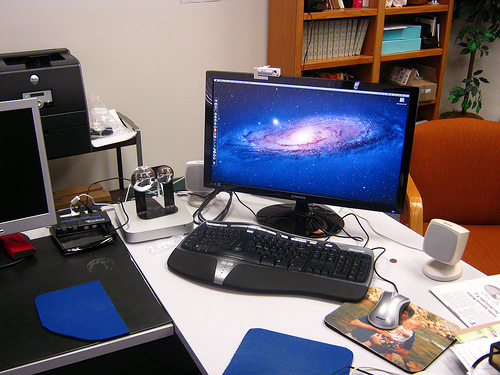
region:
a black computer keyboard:
[166, 217, 374, 304]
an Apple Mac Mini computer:
[113, 189, 195, 244]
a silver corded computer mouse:
[368, 287, 411, 329]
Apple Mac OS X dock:
[212, 97, 217, 168]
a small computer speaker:
[419, 217, 468, 281]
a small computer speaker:
[183, 158, 216, 206]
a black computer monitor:
[201, 68, 421, 239]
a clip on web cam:
[252, 64, 281, 81]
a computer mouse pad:
[324, 283, 461, 370]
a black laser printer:
[2, 43, 90, 158]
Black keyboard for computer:
[165, 216, 375, 302]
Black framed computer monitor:
[200, 63, 415, 213]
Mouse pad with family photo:
[321, 282, 458, 370]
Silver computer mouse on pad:
[365, 287, 413, 332]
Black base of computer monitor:
[253, 200, 345, 237]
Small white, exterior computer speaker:
[420, 216, 472, 283]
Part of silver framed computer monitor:
[0, 96, 60, 231]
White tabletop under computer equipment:
[102, 180, 480, 372]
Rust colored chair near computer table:
[405, 115, 496, 271]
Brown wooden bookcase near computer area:
[266, 0, 454, 118]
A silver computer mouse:
[364, 284, 414, 345]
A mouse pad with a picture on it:
[321, 277, 465, 373]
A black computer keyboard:
[165, 215, 380, 306]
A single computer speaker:
[416, 216, 474, 286]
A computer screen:
[199, 71, 419, 219]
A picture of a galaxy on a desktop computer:
[202, 78, 412, 208]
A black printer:
[0, 42, 94, 162]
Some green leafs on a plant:
[446, 68, 491, 115]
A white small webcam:
[251, 64, 283, 81]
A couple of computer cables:
[188, 181, 241, 226]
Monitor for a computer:
[203, 68, 420, 214]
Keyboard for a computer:
[165, 221, 375, 306]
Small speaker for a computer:
[423, 216, 468, 281]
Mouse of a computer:
[367, 291, 412, 332]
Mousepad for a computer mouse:
[221, 326, 354, 373]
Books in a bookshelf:
[300, 18, 372, 58]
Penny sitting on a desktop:
[390, 256, 397, 261]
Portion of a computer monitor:
[0, 96, 59, 240]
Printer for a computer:
[0, 46, 92, 153]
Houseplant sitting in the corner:
[438, 0, 498, 120]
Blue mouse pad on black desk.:
[35, 276, 126, 342]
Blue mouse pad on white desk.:
[218, 323, 353, 373]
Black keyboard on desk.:
[165, 212, 375, 305]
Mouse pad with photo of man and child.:
[320, 281, 462, 372]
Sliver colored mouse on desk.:
[365, 283, 405, 328]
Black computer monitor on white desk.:
[202, 68, 420, 233]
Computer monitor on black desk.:
[0, 95, 56, 261]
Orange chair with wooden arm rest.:
[407, 117, 497, 272]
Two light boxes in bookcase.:
[376, 26, 421, 53]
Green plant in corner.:
[445, 4, 496, 117]